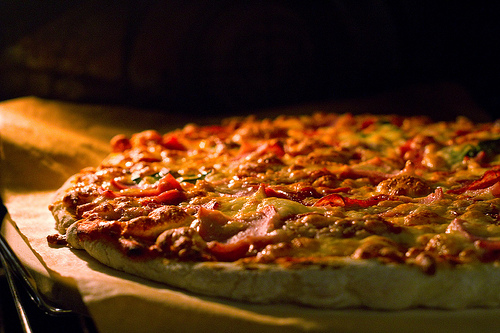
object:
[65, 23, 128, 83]
brick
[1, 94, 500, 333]
cloth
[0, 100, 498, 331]
table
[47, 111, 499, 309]
cheese